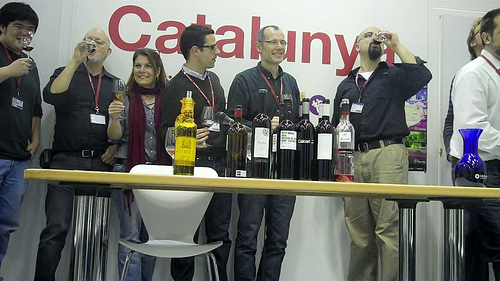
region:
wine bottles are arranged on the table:
[24, 86, 499, 279]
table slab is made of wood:
[21, 168, 498, 279]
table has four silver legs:
[23, 167, 499, 278]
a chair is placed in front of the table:
[23, 160, 498, 280]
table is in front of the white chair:
[17, 158, 494, 280]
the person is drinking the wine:
[331, 26, 432, 279]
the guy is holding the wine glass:
[1, 5, 43, 279]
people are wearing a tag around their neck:
[1, 2, 498, 277]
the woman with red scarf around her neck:
[109, 48, 166, 280]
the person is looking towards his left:
[162, 24, 232, 279]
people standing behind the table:
[1, 0, 499, 279]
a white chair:
[111, 157, 228, 279]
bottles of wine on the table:
[163, 85, 362, 181]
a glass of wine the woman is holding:
[111, 76, 130, 122]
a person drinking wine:
[328, 24, 439, 279]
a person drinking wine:
[34, 25, 124, 276]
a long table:
[20, 165, 499, 277]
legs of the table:
[66, 185, 113, 279]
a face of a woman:
[130, 58, 156, 88]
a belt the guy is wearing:
[353, 135, 409, 155]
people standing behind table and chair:
[5, 5, 491, 270]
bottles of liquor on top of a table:
[160, 81, 362, 203]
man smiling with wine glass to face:
[3, 2, 43, 240]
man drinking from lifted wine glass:
[43, 26, 123, 167]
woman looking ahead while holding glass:
[105, 46, 166, 160]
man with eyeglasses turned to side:
[170, 22, 227, 169]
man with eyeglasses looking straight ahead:
[235, 22, 300, 127]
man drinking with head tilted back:
[323, 21, 434, 184]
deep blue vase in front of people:
[441, 9, 496, 189]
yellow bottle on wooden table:
[171, 85, 198, 172]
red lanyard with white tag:
[79, 72, 114, 132]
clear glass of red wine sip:
[17, 28, 44, 63]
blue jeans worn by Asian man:
[2, 159, 40, 264]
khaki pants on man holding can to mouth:
[342, 135, 411, 277]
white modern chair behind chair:
[112, 159, 249, 276]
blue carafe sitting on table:
[451, 123, 493, 183]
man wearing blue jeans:
[233, 188, 300, 274]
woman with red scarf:
[104, 47, 190, 269]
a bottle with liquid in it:
[175, 97, 190, 164]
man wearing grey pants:
[235, 195, 290, 276]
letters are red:
[294, 35, 348, 64]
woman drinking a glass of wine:
[107, 49, 169, 279]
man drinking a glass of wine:
[1, 1, 43, 280]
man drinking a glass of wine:
[35, 29, 120, 279]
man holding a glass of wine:
[156, 22, 227, 279]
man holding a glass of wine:
[226, 26, 301, 280]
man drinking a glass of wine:
[334, 28, 432, 280]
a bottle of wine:
[225, 103, 247, 178]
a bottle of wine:
[250, 87, 270, 177]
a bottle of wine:
[275, 93, 297, 179]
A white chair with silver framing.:
[110, 166, 240, 279]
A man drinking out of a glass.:
[338, 25, 416, 277]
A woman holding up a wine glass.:
[105, 48, 175, 279]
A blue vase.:
[455, 123, 487, 198]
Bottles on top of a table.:
[148, 78, 388, 199]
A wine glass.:
[20, 33, 37, 68]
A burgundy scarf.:
[127, 78, 164, 164]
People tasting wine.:
[3, 5, 490, 248]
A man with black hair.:
[169, 21, 235, 264]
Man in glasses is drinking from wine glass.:
[42, 28, 125, 280]